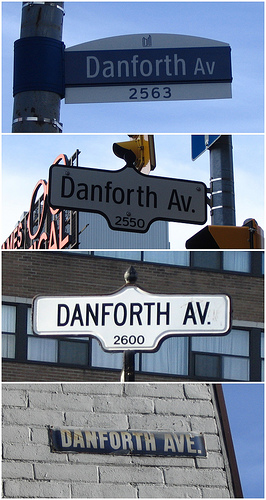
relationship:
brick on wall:
[0, 407, 63, 428] [1, 381, 233, 498]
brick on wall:
[63, 410, 132, 433] [1, 381, 233, 498]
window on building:
[191, 327, 251, 356] [1, 252, 263, 381]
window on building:
[3, 301, 24, 363] [1, 252, 263, 381]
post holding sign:
[14, 1, 63, 134] [65, 34, 234, 104]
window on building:
[257, 330, 264, 377] [1, 252, 263, 381]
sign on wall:
[45, 426, 207, 460] [1, 381, 233, 498]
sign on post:
[65, 34, 234, 104] [14, 1, 63, 134]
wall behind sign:
[1, 381, 233, 498] [65, 34, 234, 104]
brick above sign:
[63, 410, 132, 433] [45, 426, 207, 460]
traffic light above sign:
[111, 132, 158, 173] [49, 161, 208, 235]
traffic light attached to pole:
[111, 132, 158, 173] [210, 134, 237, 229]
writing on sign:
[163, 432, 197, 454] [45, 426, 207, 460]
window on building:
[26, 308, 59, 361] [1, 252, 263, 381]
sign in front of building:
[49, 161, 208, 235] [6, 191, 166, 250]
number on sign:
[114, 212, 147, 230] [49, 161, 208, 235]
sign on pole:
[49, 161, 208, 235] [210, 134, 237, 229]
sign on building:
[45, 426, 207, 460] [3, 384, 235, 499]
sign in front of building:
[30, 283, 229, 350] [1, 252, 263, 381]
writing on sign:
[58, 301, 209, 328] [30, 283, 229, 350]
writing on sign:
[59, 172, 196, 216] [49, 161, 208, 235]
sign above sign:
[30, 283, 229, 350] [45, 426, 207, 460]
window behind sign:
[191, 327, 251, 356] [30, 283, 229, 350]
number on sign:
[113, 333, 146, 345] [30, 283, 229, 350]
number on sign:
[128, 83, 173, 99] [65, 34, 234, 104]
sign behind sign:
[3, 150, 91, 250] [49, 161, 208, 235]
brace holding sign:
[204, 174, 233, 185] [49, 161, 208, 235]